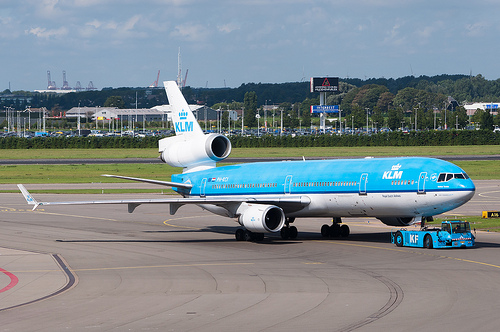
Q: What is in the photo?
A: A plane.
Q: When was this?
A: Daytime.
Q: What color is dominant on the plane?
A: Blue.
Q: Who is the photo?
A: Nobody.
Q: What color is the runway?
A: Grey.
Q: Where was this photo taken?
A: Airport.